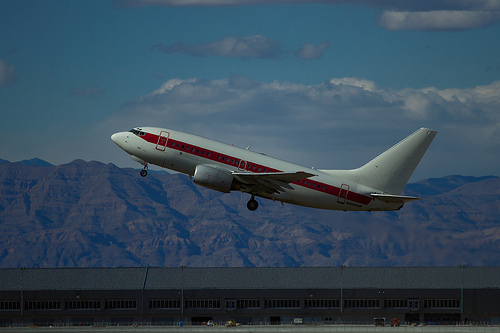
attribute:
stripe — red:
[139, 130, 373, 205]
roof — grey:
[17, 237, 499, 289]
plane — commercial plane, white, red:
[108, 118, 436, 212]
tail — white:
[319, 125, 439, 195]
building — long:
[0, 269, 489, 331]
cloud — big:
[35, 76, 497, 189]